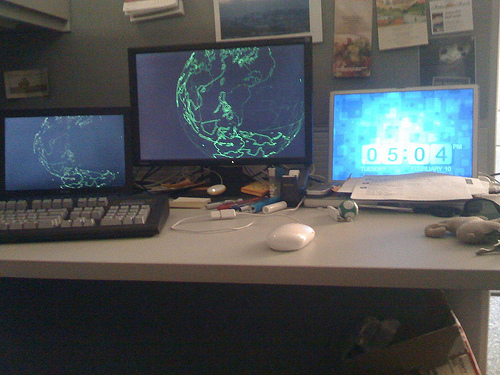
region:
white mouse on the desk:
[264, 221, 314, 252]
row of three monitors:
[2, 34, 493, 211]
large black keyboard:
[1, 189, 193, 248]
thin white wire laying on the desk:
[166, 198, 271, 245]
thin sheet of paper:
[347, 166, 484, 213]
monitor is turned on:
[130, 36, 317, 177]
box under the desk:
[309, 298, 482, 373]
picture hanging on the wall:
[211, 3, 326, 48]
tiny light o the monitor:
[224, 154, 243, 169]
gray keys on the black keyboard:
[1, 190, 173, 244]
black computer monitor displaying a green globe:
[126, 33, 313, 165]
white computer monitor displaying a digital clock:
[328, 83, 480, 189]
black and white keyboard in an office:
[0, 195, 170, 240]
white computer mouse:
[169, 194, 316, 253]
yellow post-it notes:
[168, 196, 212, 208]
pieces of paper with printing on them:
[334, 177, 492, 201]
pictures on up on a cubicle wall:
[203, 0, 475, 85]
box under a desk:
[334, 290, 489, 373]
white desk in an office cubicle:
[0, 186, 499, 291]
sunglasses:
[460, 196, 499, 221]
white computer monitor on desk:
[331, 77, 487, 179]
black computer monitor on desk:
[120, 33, 322, 179]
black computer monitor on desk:
[1, 106, 140, 198]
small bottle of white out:
[207, 204, 241, 223]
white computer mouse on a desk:
[258, 213, 319, 268]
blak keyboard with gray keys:
[2, 192, 168, 238]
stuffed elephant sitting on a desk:
[425, 208, 497, 260]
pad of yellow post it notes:
[167, 187, 216, 216]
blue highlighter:
[240, 197, 290, 212]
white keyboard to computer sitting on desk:
[336, 172, 498, 194]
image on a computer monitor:
[128, 44, 316, 170]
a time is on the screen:
[362, 145, 452, 168]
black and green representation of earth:
[170, 53, 300, 158]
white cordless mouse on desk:
[268, 217, 318, 255]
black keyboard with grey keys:
[2, 190, 164, 240]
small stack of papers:
[342, 173, 484, 208]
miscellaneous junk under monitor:
[153, 170, 314, 213]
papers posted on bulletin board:
[330, 0, 485, 84]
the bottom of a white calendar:
[119, 1, 188, 23]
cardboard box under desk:
[310, 296, 469, 373]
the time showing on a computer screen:
[362, 122, 459, 171]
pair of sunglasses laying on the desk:
[459, 196, 498, 220]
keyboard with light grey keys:
[3, 185, 167, 236]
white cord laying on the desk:
[162, 206, 257, 233]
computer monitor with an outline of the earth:
[123, 37, 316, 168]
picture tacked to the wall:
[416, 39, 496, 89]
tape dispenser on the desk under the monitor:
[284, 168, 304, 203]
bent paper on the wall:
[3, 62, 58, 100]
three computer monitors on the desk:
[1, 45, 493, 219]